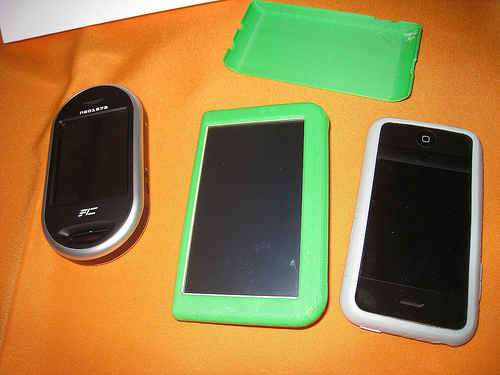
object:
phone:
[41, 83, 151, 263]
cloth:
[2, 2, 496, 373]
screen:
[52, 106, 133, 209]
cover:
[220, 1, 422, 103]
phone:
[339, 114, 481, 348]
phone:
[169, 103, 331, 329]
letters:
[77, 103, 111, 117]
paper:
[1, 2, 223, 45]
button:
[416, 128, 438, 148]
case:
[340, 116, 485, 346]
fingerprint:
[289, 256, 298, 275]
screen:
[181, 118, 306, 299]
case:
[169, 101, 331, 329]